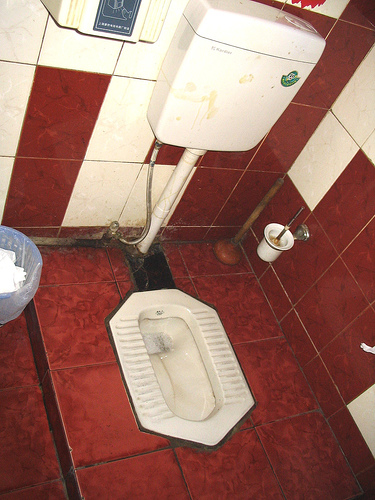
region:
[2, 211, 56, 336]
a blue trash bin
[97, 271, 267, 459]
a white in ground urinal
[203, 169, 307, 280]
an old dirty plunger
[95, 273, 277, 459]
a white men's urinal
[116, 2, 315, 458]
a white bathroom urinal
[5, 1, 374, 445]
an old dirty bathroom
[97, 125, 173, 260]
a dirty toilet line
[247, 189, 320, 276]
a dirty toilet brush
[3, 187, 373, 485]
a tile bathroom floor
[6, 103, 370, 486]
a red and white tile bathroom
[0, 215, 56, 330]
Waste basket next to toilet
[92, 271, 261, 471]
Toilet seat and bowl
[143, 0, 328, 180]
Water reservoir tank for toilet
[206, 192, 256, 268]
Rubber ended toilet plunger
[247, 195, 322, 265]
Toilet cleaning scrub brush and bowl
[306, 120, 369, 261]
Red and white tile on walls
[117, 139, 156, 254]
Water supply hose for reservoir tank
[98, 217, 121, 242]
Water supply hose cut off valve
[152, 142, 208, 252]
Water supply line from reservoir tank to bowl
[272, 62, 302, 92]
Green sticker on water reservoir tank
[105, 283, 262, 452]
Toilet is in the floor.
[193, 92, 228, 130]
Stains on the toilet bowl.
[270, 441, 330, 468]
The floor is red.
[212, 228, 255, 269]
Plunger on the floor.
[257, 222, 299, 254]
Toilet bowl cleaner in a container.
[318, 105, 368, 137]
White tile on the wall.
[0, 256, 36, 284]
Tissues in a trashcan.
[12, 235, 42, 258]
The trashcan is blue.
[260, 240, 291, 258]
The toilet bowl cleaner container is white.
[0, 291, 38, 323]
The trash bag is clear.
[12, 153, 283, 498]
this is not in the USA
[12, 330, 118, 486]
the tile is red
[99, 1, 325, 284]
this is very unsanitary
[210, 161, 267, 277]
the plunger is red with a wood handle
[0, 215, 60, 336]
garbage goes in this basket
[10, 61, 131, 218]
these tiles are red and white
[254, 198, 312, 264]
this is the cleaning brush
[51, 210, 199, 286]
many dust bunnies are on these pipes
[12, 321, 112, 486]
there is a step down right here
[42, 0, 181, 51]
dry your hands here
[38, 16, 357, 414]
photograph of bathroom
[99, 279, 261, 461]
toilet recessed in ground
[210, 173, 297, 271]
plunger in bathroom corner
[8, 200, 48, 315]
waste basket with plastic liner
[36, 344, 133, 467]
red square tile on bathroom floor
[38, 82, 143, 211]
red and white tiles on walls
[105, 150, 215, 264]
plumbing for toilet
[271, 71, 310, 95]
green sticker on white toilet tank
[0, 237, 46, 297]
white paper in white basket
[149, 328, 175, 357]
water in toilet bowl